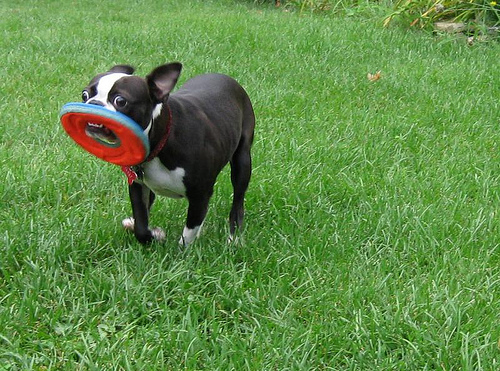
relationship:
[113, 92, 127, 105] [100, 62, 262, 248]
eye of dog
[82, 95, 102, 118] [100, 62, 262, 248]
nose of dog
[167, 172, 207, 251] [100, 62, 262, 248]
leg of dog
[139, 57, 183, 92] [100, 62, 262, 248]
ear of dog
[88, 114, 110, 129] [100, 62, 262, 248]
teeth of dog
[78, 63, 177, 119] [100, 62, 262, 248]
head of dog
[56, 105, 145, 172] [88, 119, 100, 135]
toy in mouth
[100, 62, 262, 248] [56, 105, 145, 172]
dog has toy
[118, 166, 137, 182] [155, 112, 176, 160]
tag on collar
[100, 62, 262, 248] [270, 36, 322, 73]
dog in grass